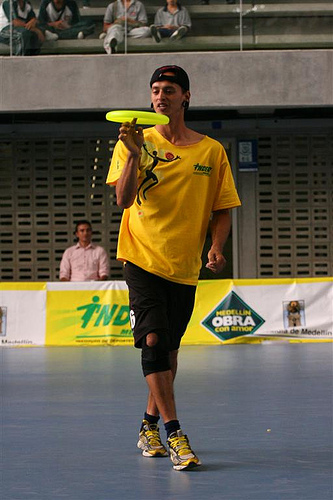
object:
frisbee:
[104, 107, 171, 126]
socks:
[165, 419, 180, 434]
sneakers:
[165, 430, 199, 472]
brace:
[140, 331, 171, 378]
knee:
[143, 331, 165, 358]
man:
[59, 220, 110, 281]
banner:
[1, 276, 332, 347]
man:
[100, 64, 242, 473]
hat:
[148, 64, 190, 90]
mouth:
[156, 101, 169, 111]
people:
[150, 1, 193, 46]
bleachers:
[3, 2, 332, 48]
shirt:
[105, 127, 240, 286]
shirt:
[58, 239, 111, 282]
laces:
[169, 434, 191, 457]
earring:
[181, 99, 189, 111]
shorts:
[122, 260, 195, 349]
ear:
[184, 89, 191, 104]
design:
[137, 142, 181, 206]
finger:
[131, 114, 138, 131]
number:
[128, 307, 137, 331]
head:
[149, 62, 191, 119]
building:
[1, 0, 333, 281]